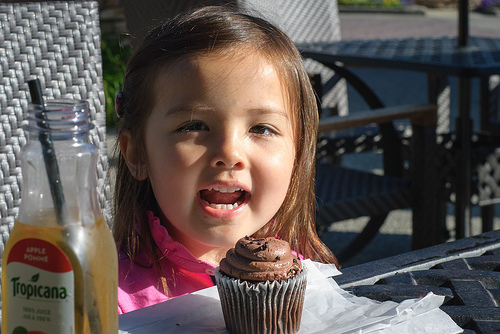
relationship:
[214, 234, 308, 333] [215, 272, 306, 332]
cupcake in wrapper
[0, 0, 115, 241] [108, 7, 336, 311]
chair behind girl